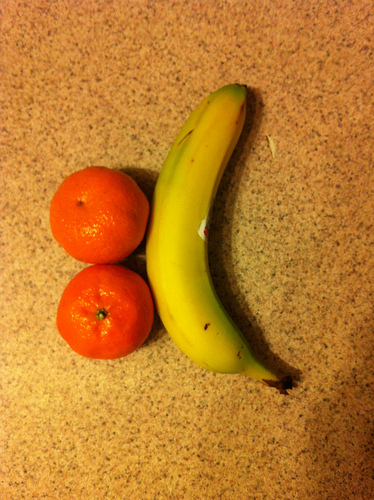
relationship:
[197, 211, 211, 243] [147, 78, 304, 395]
sticker on banana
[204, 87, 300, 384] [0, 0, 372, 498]
shadow falls on floor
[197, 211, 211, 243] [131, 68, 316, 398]
sticker on banana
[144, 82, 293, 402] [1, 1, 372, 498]
fruit on countertop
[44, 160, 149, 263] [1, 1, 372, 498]
fruit on countertop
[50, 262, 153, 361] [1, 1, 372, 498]
fruit on countertop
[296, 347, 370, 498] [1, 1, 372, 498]
shadow on countertop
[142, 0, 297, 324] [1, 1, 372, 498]
banana on countertop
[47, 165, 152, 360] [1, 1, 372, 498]
tangerines on countertop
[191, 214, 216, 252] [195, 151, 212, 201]
sticker on banana peel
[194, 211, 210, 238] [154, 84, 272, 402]
sticker on banana